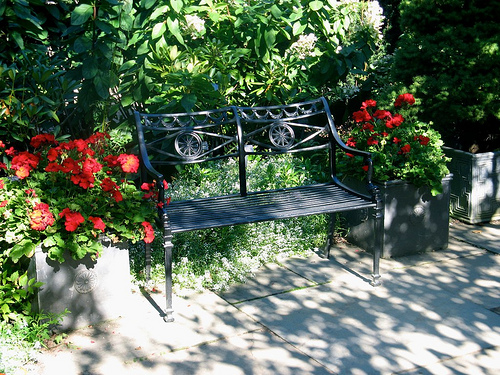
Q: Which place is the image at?
A: It is at the sidewalk.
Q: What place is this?
A: It is a sidewalk.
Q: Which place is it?
A: It is a sidewalk.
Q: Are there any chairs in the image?
A: No, there are no chairs.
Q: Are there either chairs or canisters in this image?
A: No, there are no chairs or canisters.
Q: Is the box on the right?
A: Yes, the box is on the right of the image.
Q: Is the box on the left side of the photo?
A: No, the box is on the right of the image.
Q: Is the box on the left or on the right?
A: The box is on the right of the image.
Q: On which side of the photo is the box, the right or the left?
A: The box is on the right of the image.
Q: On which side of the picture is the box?
A: The box is on the right of the image.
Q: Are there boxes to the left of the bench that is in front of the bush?
A: No, the box is to the right of the bench.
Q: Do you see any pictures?
A: No, there are no pictures.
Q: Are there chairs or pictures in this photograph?
A: No, there are no pictures or chairs.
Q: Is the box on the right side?
A: Yes, the box is on the right of the image.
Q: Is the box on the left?
A: No, the box is on the right of the image.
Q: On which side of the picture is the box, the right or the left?
A: The box is on the right of the image.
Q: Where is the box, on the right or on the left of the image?
A: The box is on the right of the image.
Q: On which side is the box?
A: The box is on the right of the image.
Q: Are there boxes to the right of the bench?
A: Yes, there is a box to the right of the bench.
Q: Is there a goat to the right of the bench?
A: No, there is a box to the right of the bench.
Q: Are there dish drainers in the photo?
A: No, there are no dish drainers.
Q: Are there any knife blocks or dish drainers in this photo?
A: No, there are no dish drainers or knife blocks.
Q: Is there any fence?
A: No, there are no fences.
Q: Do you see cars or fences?
A: No, there are no fences or cars.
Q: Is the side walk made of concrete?
A: Yes, the side walk is made of concrete.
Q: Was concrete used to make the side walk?
A: Yes, the side walk is made of concrete.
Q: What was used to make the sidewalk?
A: The sidewalk is made of cement.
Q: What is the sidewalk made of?
A: The sidewalk is made of concrete.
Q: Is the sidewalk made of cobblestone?
A: No, the sidewalk is made of cement.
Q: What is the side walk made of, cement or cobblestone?
A: The side walk is made of cement.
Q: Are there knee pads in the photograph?
A: No, there are no knee pads.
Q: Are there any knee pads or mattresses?
A: No, there are no knee pads or mattresses.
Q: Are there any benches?
A: Yes, there is a bench.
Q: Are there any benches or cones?
A: Yes, there is a bench.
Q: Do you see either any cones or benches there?
A: Yes, there is a bench.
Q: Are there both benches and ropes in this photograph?
A: No, there is a bench but no ropes.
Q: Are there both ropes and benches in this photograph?
A: No, there is a bench but no ropes.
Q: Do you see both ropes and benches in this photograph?
A: No, there is a bench but no ropes.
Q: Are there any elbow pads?
A: No, there are no elbow pads.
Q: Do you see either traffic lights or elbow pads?
A: No, there are no elbow pads or traffic lights.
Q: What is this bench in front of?
A: The bench is in front of the shrub.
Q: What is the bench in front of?
A: The bench is in front of the shrub.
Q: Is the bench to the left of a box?
A: Yes, the bench is to the left of a box.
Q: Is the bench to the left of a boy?
A: No, the bench is to the left of a box.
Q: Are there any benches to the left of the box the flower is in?
A: Yes, there is a bench to the left of the box.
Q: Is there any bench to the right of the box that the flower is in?
A: No, the bench is to the left of the box.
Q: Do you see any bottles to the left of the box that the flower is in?
A: No, there is a bench to the left of the box.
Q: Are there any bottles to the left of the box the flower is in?
A: No, there is a bench to the left of the box.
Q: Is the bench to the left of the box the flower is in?
A: Yes, the bench is to the left of the box.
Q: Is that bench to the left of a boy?
A: No, the bench is to the left of the box.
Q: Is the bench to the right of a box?
A: No, the bench is to the left of a box.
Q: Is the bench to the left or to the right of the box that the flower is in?
A: The bench is to the left of the box.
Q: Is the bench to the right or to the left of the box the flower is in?
A: The bench is to the left of the box.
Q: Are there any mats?
A: No, there are no mats.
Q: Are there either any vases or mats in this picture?
A: No, there are no mats or vases.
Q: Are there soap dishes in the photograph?
A: No, there are no soap dishes.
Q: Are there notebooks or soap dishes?
A: No, there are no soap dishes or notebooks.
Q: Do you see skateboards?
A: No, there are no skateboards.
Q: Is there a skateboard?
A: No, there are no skateboards.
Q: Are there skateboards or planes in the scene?
A: No, there are no skateboards or planes.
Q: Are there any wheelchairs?
A: No, there are no wheelchairs.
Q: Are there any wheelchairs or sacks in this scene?
A: No, there are no wheelchairs or sacks.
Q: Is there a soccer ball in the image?
A: No, there are no soccer balls.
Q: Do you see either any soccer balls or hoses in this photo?
A: No, there are no soccer balls or hoses.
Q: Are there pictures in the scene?
A: No, there are no pictures.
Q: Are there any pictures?
A: No, there are no pictures.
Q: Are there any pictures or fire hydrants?
A: No, there are no pictures or fire hydrants.